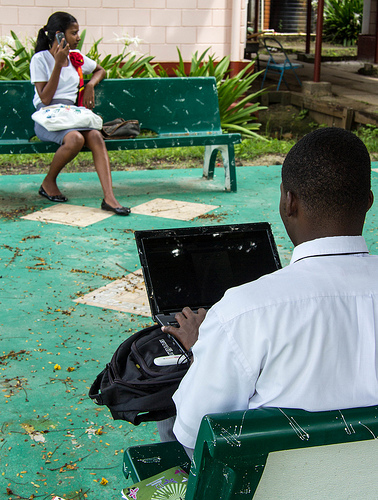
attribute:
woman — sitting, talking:
[30, 11, 132, 217]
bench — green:
[0, 78, 242, 192]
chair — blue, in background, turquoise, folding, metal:
[261, 36, 305, 92]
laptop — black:
[134, 221, 283, 362]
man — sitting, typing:
[160, 127, 376, 451]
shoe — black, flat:
[39, 186, 69, 202]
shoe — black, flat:
[101, 199, 132, 215]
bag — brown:
[101, 117, 141, 139]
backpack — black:
[88, 324, 194, 427]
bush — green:
[3, 31, 38, 81]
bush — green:
[77, 29, 158, 78]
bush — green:
[145, 51, 273, 142]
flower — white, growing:
[112, 32, 147, 48]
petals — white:
[109, 33, 147, 49]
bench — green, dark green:
[122, 405, 377, 499]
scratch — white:
[137, 455, 161, 464]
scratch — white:
[221, 410, 248, 451]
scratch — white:
[278, 407, 311, 440]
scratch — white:
[338, 409, 356, 436]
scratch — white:
[234, 482, 253, 496]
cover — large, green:
[123, 464, 193, 499]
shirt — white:
[172, 235, 377, 447]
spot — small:
[171, 248, 181, 257]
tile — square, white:
[124, 198, 221, 223]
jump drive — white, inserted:
[153, 354, 193, 368]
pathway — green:
[0, 161, 377, 500]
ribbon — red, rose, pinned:
[70, 50, 86, 108]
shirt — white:
[30, 50, 99, 104]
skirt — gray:
[34, 99, 101, 144]